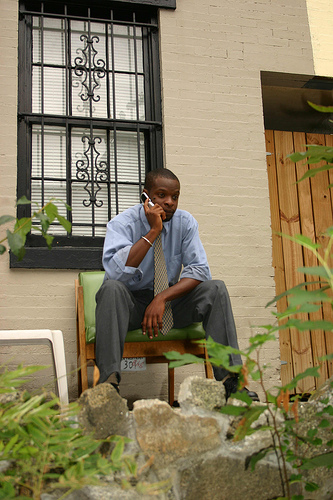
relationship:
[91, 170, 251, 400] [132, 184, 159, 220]
man talking on phone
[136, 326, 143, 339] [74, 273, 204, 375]
cushions on chair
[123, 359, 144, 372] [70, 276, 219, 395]
sign attached to chair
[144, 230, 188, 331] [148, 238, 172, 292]
tie with design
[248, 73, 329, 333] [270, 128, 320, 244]
door with boards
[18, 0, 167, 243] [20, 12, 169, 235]
grate over window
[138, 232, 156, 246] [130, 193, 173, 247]
bracelet on hand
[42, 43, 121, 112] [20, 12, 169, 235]
blinds in window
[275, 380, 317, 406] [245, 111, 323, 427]
bracket on door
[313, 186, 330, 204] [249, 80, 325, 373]
hole in door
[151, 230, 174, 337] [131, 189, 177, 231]
tie around neck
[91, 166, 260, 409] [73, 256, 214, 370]
man on chair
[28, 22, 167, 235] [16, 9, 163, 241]
grate on window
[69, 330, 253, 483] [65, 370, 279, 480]
wall of rocks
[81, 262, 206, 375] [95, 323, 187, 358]
chair with cushion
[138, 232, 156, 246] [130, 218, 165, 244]
bracelet on wrist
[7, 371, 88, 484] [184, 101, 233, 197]
plants in wall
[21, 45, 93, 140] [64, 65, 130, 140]
window has bars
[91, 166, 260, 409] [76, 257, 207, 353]
man sitting in chair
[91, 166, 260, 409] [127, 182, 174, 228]
man talking on cellphone